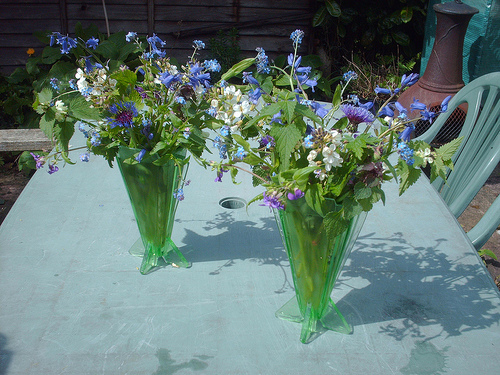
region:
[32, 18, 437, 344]
Two vases of flowers on table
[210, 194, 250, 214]
Umbrella hole in table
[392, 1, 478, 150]
Patio heater on porch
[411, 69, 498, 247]
Green chair next to table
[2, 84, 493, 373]
Green table on the patio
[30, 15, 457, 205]
Purple and white flowers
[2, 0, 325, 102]
Wooden fence in the background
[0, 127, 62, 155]
Bench behind table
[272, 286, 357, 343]
Feet on the bottom of vase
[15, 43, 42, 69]
Orange flower in the garden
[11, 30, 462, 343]
two vases on top of table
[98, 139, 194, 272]
clear green glass vase with flowers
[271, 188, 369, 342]
clear green glass vase with flowers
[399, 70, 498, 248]
plastic chair next to table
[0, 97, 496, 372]
white table next to chair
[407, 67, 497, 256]
plastic chair is white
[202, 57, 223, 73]
blue flower next to blue flower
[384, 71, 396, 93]
blue flower next to blue flower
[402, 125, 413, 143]
blue flower next to blue flower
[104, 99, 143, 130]
blue flower next to blue flower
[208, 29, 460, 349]
A vase full of flowers.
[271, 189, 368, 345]
A green colored vase.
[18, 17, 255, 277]
Blue flowers in a vase.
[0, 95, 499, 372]
A green plastic tabletop.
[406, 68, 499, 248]
A green lawn chair.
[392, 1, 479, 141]
A small brown fireplace.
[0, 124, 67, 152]
A piece of wood.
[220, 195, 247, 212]
A hole for an umbrella.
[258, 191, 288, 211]
A bright purple flower.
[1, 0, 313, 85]
A brown wood fence.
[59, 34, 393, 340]
two vases of flowers on the table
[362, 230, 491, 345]
shadow of the flowers on the table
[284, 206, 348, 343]
green vase for the flowers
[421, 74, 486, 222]
green chair next to the table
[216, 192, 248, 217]
hole in table for the umbrella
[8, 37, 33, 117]
flowers behind the table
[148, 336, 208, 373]
table has a spot on it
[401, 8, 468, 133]
outdoor fireplace behind the chair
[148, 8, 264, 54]
wooden fence behind the table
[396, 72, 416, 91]
blue flower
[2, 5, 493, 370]
two similar vases of flowers and greens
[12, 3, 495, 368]
blue outdoor table and a chair with two vases of flowers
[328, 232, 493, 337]
shadow of a vase of flowers on a blue table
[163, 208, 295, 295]
shadow of a vase of flowers on a blue table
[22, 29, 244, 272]
blue and white flowers with greens in a clear vase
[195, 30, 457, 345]
blue and white flowers with greens in a clear vase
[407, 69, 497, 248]
blue outdoor chair by a table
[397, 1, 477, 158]
round red outdoor fire box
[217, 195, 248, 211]
umbrella hole in the middle of a table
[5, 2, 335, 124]
brown wooden privacy fence near the table